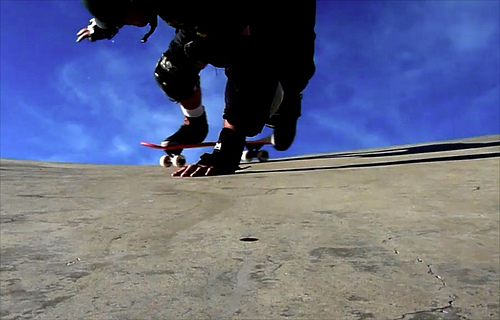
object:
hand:
[173, 157, 239, 185]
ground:
[0, 135, 500, 320]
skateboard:
[140, 132, 280, 167]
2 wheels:
[159, 155, 188, 166]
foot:
[160, 115, 210, 148]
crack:
[320, 213, 470, 318]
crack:
[0, 220, 165, 320]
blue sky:
[0, 0, 500, 166]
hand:
[76, 19, 117, 48]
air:
[0, 0, 499, 166]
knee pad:
[154, 49, 203, 102]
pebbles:
[104, 177, 326, 205]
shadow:
[238, 141, 497, 174]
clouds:
[2, 0, 500, 166]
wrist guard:
[216, 128, 246, 151]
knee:
[147, 55, 198, 99]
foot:
[270, 97, 304, 154]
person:
[78, 0, 315, 177]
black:
[226, 0, 316, 85]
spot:
[240, 236, 260, 243]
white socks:
[179, 107, 206, 116]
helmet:
[77, 0, 169, 23]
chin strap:
[139, 17, 167, 43]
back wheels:
[257, 149, 270, 161]